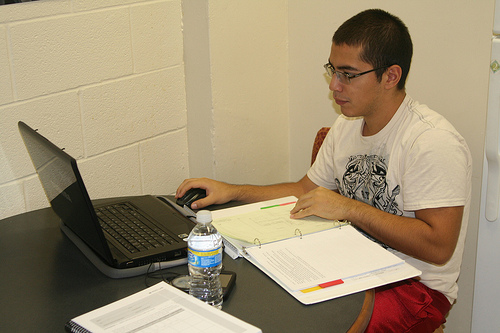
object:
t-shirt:
[305, 91, 473, 306]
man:
[174, 8, 473, 333]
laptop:
[17, 120, 225, 269]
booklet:
[195, 195, 422, 306]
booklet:
[65, 279, 263, 333]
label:
[187, 244, 223, 268]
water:
[187, 225, 222, 310]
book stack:
[65, 280, 264, 332]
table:
[0, 195, 376, 333]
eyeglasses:
[323, 61, 401, 84]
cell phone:
[184, 270, 237, 302]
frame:
[323, 62, 400, 82]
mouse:
[176, 188, 206, 208]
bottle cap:
[197, 209, 213, 222]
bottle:
[186, 209, 224, 311]